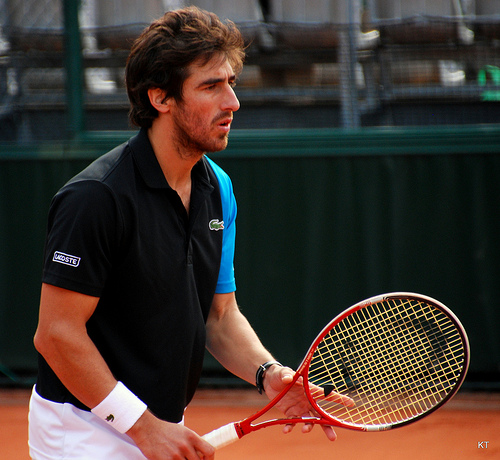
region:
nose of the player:
[214, 81, 256, 117]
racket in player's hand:
[271, 274, 468, 456]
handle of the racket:
[197, 403, 252, 458]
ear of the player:
[141, 85, 178, 117]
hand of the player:
[173, 422, 210, 453]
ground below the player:
[428, 421, 470, 453]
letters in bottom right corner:
[470, 419, 497, 459]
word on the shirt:
[44, 235, 101, 282]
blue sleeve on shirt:
[206, 178, 258, 288]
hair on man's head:
[116, 13, 244, 86]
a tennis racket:
[177, 286, 472, 440]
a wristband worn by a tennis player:
[75, 374, 148, 439]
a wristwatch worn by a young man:
[250, 354, 292, 392]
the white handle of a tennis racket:
[197, 419, 258, 446]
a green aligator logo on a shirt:
[202, 215, 229, 236]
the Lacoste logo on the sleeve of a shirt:
[51, 248, 81, 274]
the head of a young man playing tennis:
[126, 13, 258, 154]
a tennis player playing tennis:
[40, 18, 390, 317]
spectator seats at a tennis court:
[264, 6, 474, 108]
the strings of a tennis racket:
[337, 323, 442, 390]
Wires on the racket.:
[367, 369, 421, 402]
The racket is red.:
[266, 381, 324, 430]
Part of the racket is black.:
[392, 414, 438, 433]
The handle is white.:
[198, 428, 241, 453]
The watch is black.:
[249, 346, 278, 388]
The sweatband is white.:
[101, 400, 141, 416]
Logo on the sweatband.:
[87, 410, 124, 426]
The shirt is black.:
[130, 279, 172, 311]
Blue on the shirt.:
[212, 195, 241, 222]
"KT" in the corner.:
[462, 431, 498, 459]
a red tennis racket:
[309, 316, 372, 453]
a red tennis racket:
[302, 357, 349, 447]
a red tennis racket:
[261, 330, 324, 449]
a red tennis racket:
[291, 349, 306, 391]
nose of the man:
[218, 78, 250, 114]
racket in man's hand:
[293, 285, 471, 455]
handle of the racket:
[195, 417, 241, 450]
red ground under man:
[398, 424, 460, 459]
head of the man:
[119, 14, 272, 159]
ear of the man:
[135, 69, 198, 134]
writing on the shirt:
[46, 232, 85, 284]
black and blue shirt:
[170, 170, 262, 267]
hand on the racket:
[167, 404, 222, 459]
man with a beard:
[154, 41, 262, 138]